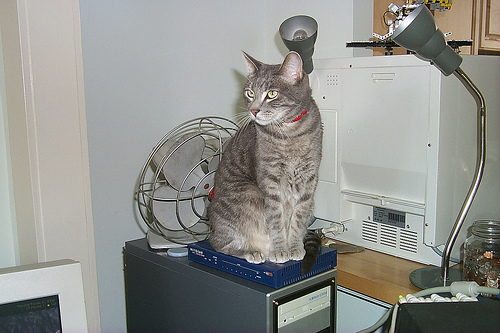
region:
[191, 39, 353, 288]
this is a cat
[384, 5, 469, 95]
this is a lamp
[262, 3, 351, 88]
this is a lamp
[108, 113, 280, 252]
this is a fan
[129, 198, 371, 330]
this is a computer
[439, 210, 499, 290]
this is a bottle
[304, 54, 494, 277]
this is a maachine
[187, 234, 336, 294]
this is a maachine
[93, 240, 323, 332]
this is a maachine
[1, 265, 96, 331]
this is a maachine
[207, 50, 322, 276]
a gray cat sitting on a blue book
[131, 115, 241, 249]
a gray fan behind a cat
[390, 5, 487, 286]
a gray lamp on a desk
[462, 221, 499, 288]
a jar on a desk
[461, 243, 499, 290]
coins inside a glass jar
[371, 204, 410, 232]
a gray metallic sticker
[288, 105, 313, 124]
a red collar on a cat's neck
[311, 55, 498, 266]
the back of a white appliance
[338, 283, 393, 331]
a white notebook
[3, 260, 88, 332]
edge of a white laminated frame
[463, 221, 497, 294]
clear glass jar with change in it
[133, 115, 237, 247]
small round metal fan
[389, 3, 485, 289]
tall silver metal desk lamp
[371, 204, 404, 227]
silver plate on the back of the fridge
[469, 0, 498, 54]
wooden cupboard door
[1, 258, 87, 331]
corner of white cardboard box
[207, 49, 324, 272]
gray cat with yellow eyes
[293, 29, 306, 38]
small light bulb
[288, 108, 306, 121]
red collar on the cat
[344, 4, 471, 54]
figure on top of the fridge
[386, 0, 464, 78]
a small head of a desk lamp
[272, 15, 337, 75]
a desk lamp that is missing a light bulb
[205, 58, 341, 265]
a grey cat with a red collar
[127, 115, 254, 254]
a small old and dusty fan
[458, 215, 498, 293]
a jar full of coins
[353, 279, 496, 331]
a grey long cable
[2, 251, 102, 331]
an old computer screen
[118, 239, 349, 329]
a desktop computer tower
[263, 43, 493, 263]
a large uknown machine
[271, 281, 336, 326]
a CD drive on a computer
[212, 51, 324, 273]
ray cat sitting on a blue box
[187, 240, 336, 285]
blue electronic compotent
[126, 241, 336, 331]
gray computer tower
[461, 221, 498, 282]
clear jar full of change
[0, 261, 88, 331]
computer monitor on the left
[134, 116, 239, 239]
metal fan behind the cat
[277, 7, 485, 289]
two gray lamps on the desk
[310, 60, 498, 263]
the back of a large laser printer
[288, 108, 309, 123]
the cat's red collar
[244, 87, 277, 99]
the cats open eyes